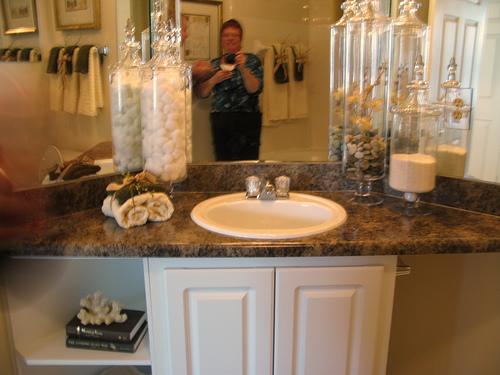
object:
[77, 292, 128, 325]
figurine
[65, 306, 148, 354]
books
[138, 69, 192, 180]
cotton balls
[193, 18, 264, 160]
lady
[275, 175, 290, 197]
knob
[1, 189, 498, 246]
countertop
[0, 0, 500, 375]
bathroom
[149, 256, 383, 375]
doors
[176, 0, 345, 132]
walls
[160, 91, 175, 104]
ball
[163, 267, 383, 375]
cupboards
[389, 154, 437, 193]
soap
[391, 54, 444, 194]
jar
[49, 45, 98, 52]
rack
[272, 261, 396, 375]
drawer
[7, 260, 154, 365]
shelf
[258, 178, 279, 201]
faucet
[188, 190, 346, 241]
sink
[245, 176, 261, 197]
knob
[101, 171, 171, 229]
towel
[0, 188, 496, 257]
counter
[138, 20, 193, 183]
jar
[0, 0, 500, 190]
mirror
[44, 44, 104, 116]
towels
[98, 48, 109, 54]
rack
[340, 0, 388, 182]
jars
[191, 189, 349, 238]
bathroom sink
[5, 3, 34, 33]
picture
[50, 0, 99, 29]
picture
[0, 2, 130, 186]
wall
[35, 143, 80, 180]
toilet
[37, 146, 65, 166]
seat